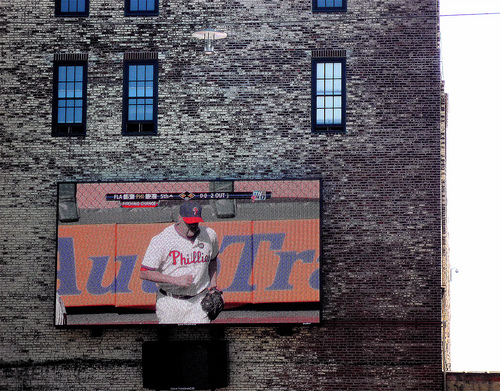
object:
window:
[50, 54, 87, 137]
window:
[120, 52, 156, 136]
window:
[309, 48, 346, 130]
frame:
[312, 52, 345, 133]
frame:
[121, 54, 160, 134]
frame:
[53, 54, 87, 134]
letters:
[168, 249, 210, 265]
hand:
[178, 273, 194, 290]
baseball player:
[138, 201, 224, 324]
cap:
[179, 201, 206, 224]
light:
[191, 27, 228, 56]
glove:
[199, 287, 226, 320]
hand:
[206, 286, 223, 296]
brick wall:
[0, 0, 447, 390]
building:
[1, 1, 500, 390]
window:
[117, 50, 164, 135]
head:
[177, 200, 204, 238]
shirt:
[142, 222, 219, 297]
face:
[180, 219, 199, 237]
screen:
[55, 178, 322, 329]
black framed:
[310, 50, 347, 134]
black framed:
[120, 51, 160, 137]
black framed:
[51, 52, 88, 136]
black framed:
[124, 0, 159, 17]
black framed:
[52, 0, 90, 17]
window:
[43, 49, 96, 139]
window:
[119, 45, 168, 147]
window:
[294, 45, 356, 137]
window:
[309, 0, 347, 13]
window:
[122, 0, 160, 16]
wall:
[0, 0, 442, 390]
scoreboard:
[104, 190, 275, 206]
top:
[58, 180, 319, 204]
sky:
[0, 0, 499, 115]